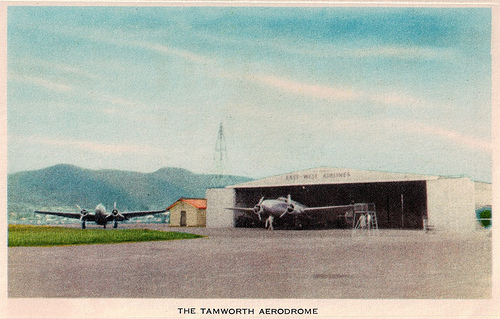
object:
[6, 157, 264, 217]
hills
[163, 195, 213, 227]
building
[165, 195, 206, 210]
roof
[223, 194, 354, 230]
plane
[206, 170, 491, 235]
hanger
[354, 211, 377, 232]
ladder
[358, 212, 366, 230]
people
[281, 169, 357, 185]
letters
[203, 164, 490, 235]
hangar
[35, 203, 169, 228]
plane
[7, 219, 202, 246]
grass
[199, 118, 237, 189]
tower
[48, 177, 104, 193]
trees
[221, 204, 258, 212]
left wing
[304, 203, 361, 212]
right wing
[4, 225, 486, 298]
runway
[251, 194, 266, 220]
propeller blade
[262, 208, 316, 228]
underside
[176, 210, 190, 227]
door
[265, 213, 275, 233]
person